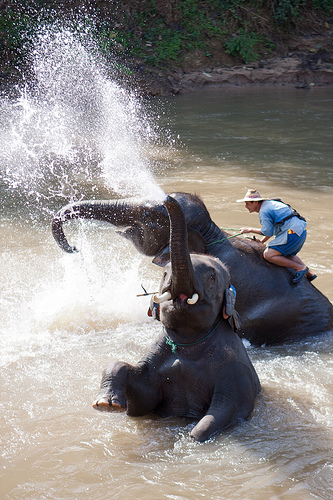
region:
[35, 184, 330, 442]
two elephants in water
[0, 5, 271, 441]
elephant squirting water out nose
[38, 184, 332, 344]
elephant with man on back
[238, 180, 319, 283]
man on elephant's back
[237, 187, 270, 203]
hat on man's head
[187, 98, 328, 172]
a body of water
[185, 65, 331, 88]
rocky land next to water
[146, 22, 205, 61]
green plant life on side terrain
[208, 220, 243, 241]
rope man hangs onto elephant with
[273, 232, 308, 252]
blue shorts on elephant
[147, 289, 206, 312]
The tusks are white.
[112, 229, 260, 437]
The elephant is grey.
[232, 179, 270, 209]
The hat is tan.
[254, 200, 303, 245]
His shirt is blue.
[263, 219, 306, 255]
His shorts are blue.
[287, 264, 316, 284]
The shoes are blue.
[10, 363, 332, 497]
The water is brown.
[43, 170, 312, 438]
The elephants are in the water.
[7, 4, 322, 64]
The bushes are green.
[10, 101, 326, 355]
these are elephants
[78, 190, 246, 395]
these elephants are gray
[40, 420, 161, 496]
the water here is brown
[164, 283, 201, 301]
the elephant has tusks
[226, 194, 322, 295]
this man is riding the elephant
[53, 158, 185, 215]
the elephant is shooting water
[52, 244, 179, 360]
the elephant is splashing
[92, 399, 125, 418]
the elephants hooves are tan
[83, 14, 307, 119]
this is a riverside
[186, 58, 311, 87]
the river side is made of mud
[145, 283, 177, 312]
White tusk on an elephant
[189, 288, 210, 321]
White tusk on an elephant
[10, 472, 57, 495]
Ripples in the water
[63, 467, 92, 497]
Ripples in the water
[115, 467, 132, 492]
Ripples in the water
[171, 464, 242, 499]
Ripples in the water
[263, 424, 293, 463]
Ripples in the water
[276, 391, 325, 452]
Ripples in the water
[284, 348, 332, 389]
Ripples in the water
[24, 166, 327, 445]
Elephants in the water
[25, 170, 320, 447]
elephants and a man playing the water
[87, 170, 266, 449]
an elephant shooting water out of it's trunk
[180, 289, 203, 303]
the tusk of an elephant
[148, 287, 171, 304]
the tusk of an elephant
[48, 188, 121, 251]
a trunk of an elephant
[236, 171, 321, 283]
a man on the back of an elephant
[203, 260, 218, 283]
an eye of an elephant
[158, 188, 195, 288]
the trunk of an elephant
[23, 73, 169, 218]
the water spraying out of a trunk of an elephant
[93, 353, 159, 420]
the leg of an elephant